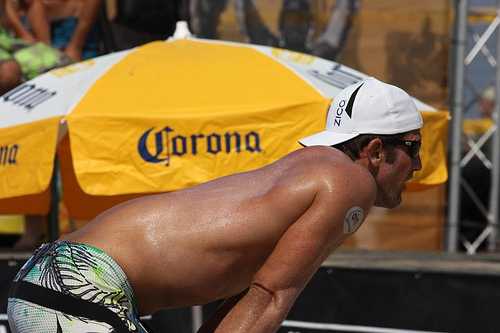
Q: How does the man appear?
A: Shirtless.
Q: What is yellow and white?
A: An umbrella.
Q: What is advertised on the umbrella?
A: Corona.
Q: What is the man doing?
A: Leaning forward.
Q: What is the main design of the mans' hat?
A: All white.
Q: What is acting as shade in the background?
A: The top of a yellow and white umbrella.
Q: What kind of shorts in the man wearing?
A: Board shorts.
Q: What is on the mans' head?
A: A white cap.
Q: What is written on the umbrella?
A: Corona beer company.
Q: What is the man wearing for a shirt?
A: He is not wearing a shirt.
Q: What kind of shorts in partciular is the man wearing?
A: Swim trunks.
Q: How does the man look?
A: Wet.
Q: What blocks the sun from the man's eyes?
A: Sunglasses.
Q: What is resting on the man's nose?
A: Sunglasses.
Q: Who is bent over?
A: The man.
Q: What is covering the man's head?
A: A hat.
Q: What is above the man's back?
A: Umbrella.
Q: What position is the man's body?
A: Bent over.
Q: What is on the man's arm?
A: A sticker.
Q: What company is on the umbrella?
A: Corona.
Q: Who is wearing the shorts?
A: The man.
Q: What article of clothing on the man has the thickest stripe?
A: The shorts.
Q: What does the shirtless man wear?
A: A white cap.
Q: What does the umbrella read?
A: Corona.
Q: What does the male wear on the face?
A: Sunglasses.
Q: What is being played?
A: Probably beach volleyball.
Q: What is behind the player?
A: White and yellow sun umbrella.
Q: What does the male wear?
A: Shirtless with board shorts.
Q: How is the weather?
A: Sunny.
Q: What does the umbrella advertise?
A: Corona.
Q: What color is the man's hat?
A: White.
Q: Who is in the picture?
A: A man.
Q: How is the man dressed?
A: Shirtless.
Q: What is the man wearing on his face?
A: Sunglasses.